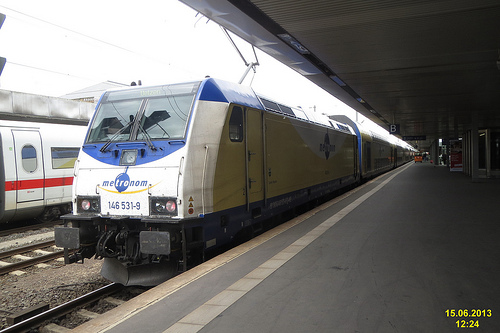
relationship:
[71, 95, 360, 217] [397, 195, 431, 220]
train in station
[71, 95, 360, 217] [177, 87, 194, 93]
train on schedule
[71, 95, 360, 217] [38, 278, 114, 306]
train on tracks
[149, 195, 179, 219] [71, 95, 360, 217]
headlights of train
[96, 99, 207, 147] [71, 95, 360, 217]
windshield of train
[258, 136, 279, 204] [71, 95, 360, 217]
door of train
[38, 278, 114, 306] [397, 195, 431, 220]
tracks near station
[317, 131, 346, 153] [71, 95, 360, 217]
window on train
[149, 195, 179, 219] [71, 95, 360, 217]
headlights on train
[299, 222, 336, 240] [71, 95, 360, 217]
line above train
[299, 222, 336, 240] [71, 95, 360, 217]
line on train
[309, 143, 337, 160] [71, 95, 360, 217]
name on train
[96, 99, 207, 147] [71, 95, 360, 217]
windshield on train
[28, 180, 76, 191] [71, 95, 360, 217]
stripe on train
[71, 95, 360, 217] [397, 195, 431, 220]
train at station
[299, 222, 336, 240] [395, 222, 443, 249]
line on ground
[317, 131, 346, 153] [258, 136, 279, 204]
window on door